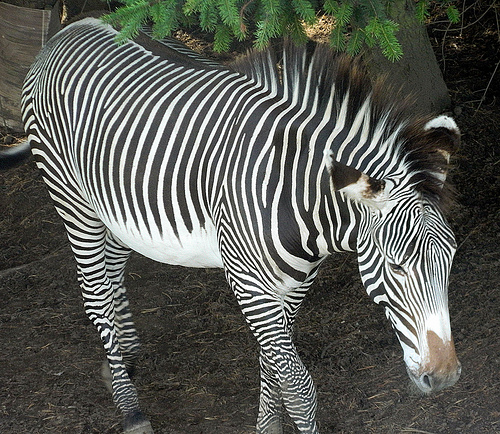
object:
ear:
[322, 155, 392, 212]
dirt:
[303, 306, 382, 411]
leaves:
[308, 307, 330, 328]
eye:
[382, 262, 409, 278]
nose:
[421, 362, 462, 388]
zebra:
[21, 10, 461, 430]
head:
[324, 117, 467, 392]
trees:
[94, 2, 461, 57]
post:
[0, 8, 59, 152]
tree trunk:
[353, 2, 445, 116]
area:
[0, 49, 490, 351]